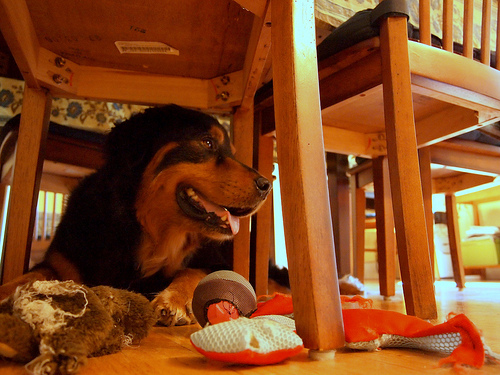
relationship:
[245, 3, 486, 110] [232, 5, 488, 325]
cushion in chair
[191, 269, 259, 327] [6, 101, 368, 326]
ball in dog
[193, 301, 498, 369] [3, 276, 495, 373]
toy in floor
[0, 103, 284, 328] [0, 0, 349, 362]
dog in chair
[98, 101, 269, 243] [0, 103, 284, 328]
head of dog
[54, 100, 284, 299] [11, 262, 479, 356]
dog playing with toys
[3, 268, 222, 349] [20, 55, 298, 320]
claws of dog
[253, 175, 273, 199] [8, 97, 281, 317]
nose of dog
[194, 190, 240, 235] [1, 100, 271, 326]
tongue of dog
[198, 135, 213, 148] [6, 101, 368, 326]
eye of dog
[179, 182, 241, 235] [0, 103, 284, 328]
teeth of dog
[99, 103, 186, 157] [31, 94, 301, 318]
ear of dog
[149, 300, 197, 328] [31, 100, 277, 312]
claws of dog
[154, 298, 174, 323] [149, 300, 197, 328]
nails of claws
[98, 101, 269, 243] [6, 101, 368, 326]
head of dog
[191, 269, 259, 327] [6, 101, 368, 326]
ball by dog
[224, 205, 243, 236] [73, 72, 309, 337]
tongue sticking out of dog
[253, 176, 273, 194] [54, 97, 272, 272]
nose of dog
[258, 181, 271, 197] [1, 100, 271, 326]
nostril of dog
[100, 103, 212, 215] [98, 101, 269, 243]
fur on head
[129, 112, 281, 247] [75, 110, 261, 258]
face of dog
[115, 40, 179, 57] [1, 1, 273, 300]
label on chair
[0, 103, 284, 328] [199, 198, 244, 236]
dog has tongue